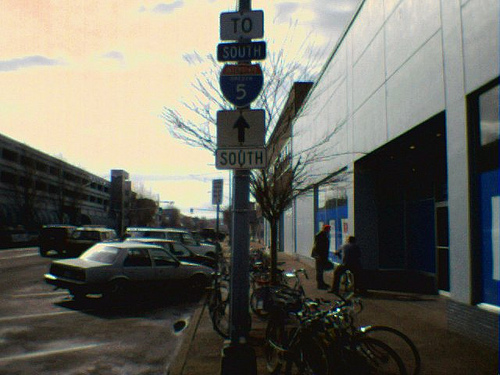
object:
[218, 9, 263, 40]
sign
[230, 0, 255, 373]
pole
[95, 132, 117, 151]
clouds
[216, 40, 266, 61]
sign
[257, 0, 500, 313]
building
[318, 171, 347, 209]
window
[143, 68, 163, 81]
clouds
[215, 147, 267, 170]
sign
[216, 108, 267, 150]
sign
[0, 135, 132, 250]
building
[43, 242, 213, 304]
car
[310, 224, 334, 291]
person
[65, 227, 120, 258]
vehicles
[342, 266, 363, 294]
bike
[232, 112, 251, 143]
arrow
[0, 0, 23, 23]
cloud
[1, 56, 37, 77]
clouds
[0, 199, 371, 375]
street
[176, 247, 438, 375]
sidewalk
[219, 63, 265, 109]
sign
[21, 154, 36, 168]
windows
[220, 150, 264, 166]
south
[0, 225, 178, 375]
road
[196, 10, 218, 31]
white clouds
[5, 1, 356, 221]
sky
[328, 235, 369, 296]
man